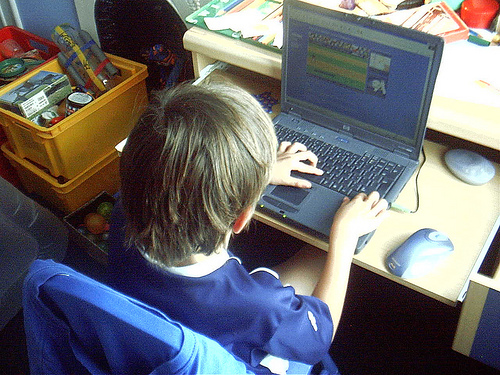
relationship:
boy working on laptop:
[93, 77, 388, 372] [233, 1, 442, 261]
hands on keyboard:
[266, 137, 386, 238] [267, 121, 411, 243]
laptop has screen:
[233, 1, 442, 261] [282, 23, 430, 134]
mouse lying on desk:
[381, 221, 463, 279] [148, 2, 496, 313]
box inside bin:
[2, 70, 76, 116] [3, 49, 159, 179]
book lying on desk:
[186, 3, 298, 57] [148, 2, 496, 313]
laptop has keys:
[233, 1, 442, 261] [270, 125, 393, 197]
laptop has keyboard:
[233, 1, 442, 261] [267, 121, 411, 243]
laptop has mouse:
[233, 1, 442, 261] [381, 221, 463, 279]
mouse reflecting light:
[381, 221, 463, 279] [413, 245, 449, 254]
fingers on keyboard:
[282, 140, 323, 191] [267, 121, 411, 243]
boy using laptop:
[93, 77, 388, 372] [233, 1, 442, 261]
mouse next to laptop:
[381, 221, 463, 279] [233, 1, 442, 261]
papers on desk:
[171, 1, 298, 67] [148, 2, 496, 313]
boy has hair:
[93, 77, 388, 372] [101, 81, 271, 270]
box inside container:
[2, 70, 76, 116] [3, 49, 159, 179]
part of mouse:
[423, 234, 432, 249] [381, 221, 463, 279]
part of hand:
[280, 152, 300, 170] [270, 140, 327, 195]